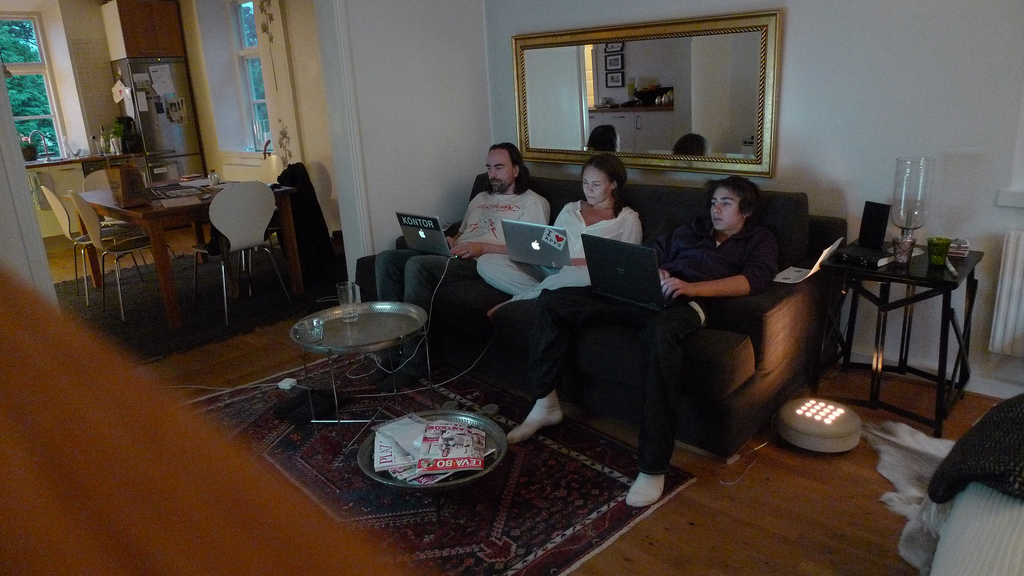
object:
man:
[369, 142, 551, 392]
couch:
[356, 172, 848, 459]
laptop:
[501, 218, 572, 269]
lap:
[477, 253, 592, 324]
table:
[290, 301, 435, 451]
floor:
[0, 224, 1005, 576]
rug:
[176, 355, 700, 576]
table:
[810, 238, 984, 439]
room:
[0, 0, 1023, 576]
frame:
[512, 7, 784, 178]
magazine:
[416, 422, 486, 474]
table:
[356, 409, 508, 528]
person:
[477, 152, 643, 321]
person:
[507, 175, 780, 507]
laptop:
[395, 211, 456, 256]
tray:
[357, 410, 508, 488]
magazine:
[374, 432, 418, 472]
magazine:
[371, 412, 433, 464]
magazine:
[389, 464, 425, 482]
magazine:
[408, 449, 496, 485]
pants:
[527, 270, 708, 476]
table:
[64, 179, 307, 329]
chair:
[41, 185, 160, 307]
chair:
[68, 189, 197, 323]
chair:
[191, 181, 294, 327]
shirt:
[455, 189, 550, 262]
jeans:
[376, 249, 485, 377]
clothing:
[477, 200, 643, 303]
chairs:
[40, 155, 293, 327]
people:
[369, 142, 780, 508]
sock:
[626, 472, 665, 507]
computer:
[581, 233, 705, 312]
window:
[0, 11, 70, 162]